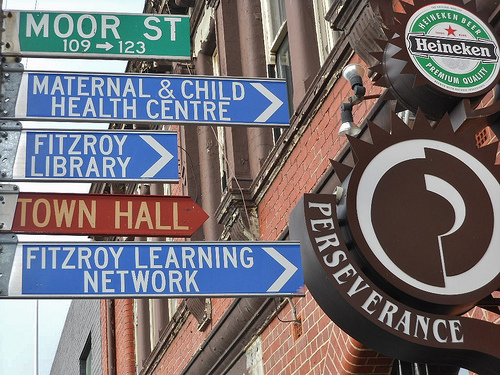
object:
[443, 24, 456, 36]
star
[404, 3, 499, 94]
sign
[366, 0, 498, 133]
sign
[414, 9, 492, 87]
german shepard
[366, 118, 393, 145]
spikes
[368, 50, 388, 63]
spikes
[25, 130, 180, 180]
blue sign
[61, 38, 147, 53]
numbers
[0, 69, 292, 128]
sign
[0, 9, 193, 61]
sign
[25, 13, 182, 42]
moor street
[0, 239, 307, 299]
sign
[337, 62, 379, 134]
spot light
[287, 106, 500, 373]
sign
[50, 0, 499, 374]
building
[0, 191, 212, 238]
sign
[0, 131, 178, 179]
sign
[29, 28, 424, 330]
center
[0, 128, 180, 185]
sign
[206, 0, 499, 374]
right